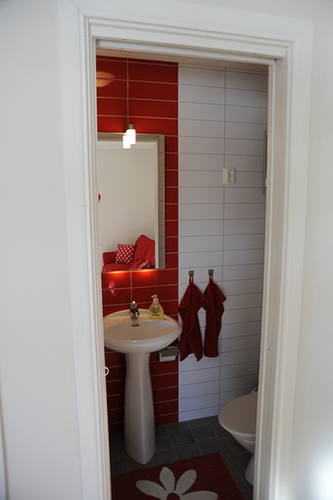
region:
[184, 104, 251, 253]
this is the wall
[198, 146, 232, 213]
the wall is white in color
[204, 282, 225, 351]
this is a towel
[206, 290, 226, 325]
the towel is red in color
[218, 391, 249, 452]
this is a toilet sink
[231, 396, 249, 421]
the sink is white in color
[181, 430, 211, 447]
this is the floor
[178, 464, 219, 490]
this is a carpet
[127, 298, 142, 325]
this is a tap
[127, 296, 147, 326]
this is a metal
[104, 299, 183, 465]
A white pedestal sink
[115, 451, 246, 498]
Red bathroom rug with a white flower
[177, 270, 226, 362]
Two red towels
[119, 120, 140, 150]
A lit light in a bathroom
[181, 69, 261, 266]
White tiled wall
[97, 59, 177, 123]
Red tiles on a wall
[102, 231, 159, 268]
A red couch with a pillow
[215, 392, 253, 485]
A white toilet in a bathroom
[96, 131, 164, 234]
A bathroom mirror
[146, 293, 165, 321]
Liquid yellow hand soap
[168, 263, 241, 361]
two red towels hanging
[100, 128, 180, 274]
reflection in the mirror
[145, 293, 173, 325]
soap on the side of sink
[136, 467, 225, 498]
flower on the rug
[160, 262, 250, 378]
towels hanging next to sink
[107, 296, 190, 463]
sink is under the mirror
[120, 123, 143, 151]
light above the mirror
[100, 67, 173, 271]
red wall in the bathroom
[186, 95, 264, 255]
white wall in bathroom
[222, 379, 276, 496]
toilet is white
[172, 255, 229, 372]
two red hand towels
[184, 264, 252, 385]
two red hand towels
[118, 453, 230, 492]
a rug on the floor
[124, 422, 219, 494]
a rug on the floor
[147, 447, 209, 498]
a rug on the floor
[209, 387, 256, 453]
this is a toilet sink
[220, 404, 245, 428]
the sink is white in color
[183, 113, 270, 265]
this is a wall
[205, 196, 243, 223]
the wall is white in color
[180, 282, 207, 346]
this is a towel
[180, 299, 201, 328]
the towel is red in color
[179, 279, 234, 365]
the towels are two in number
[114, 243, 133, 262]
this is a pillow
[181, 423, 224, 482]
this is the floor